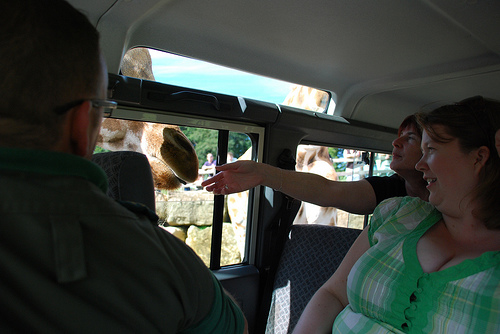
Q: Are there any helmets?
A: No, there are no helmets.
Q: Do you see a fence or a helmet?
A: No, there are no helmets or fences.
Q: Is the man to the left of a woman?
A: Yes, the man is to the left of a woman.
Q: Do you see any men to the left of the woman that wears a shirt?
A: Yes, there is a man to the left of the woman.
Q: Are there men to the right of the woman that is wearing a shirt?
A: No, the man is to the left of the woman.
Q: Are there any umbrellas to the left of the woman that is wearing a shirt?
A: No, there is a man to the left of the woman.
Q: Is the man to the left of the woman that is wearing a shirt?
A: Yes, the man is to the left of the woman.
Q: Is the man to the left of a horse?
A: No, the man is to the left of the woman.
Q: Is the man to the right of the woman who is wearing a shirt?
A: No, the man is to the left of the woman.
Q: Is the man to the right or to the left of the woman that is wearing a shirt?
A: The man is to the left of the woman.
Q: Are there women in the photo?
A: Yes, there is a woman.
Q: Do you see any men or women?
A: Yes, there is a woman.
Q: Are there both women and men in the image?
A: Yes, there are both a woman and a man.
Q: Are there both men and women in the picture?
A: Yes, there are both a woman and a man.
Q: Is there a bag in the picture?
A: No, there are no bags.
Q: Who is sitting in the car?
A: The woman is sitting in the car.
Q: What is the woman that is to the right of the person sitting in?
A: The woman is sitting in the car.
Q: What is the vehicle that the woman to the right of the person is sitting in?
A: The vehicle is a car.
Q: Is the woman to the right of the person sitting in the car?
A: Yes, the woman is sitting in the car.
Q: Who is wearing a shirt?
A: The woman is wearing a shirt.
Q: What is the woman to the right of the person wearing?
A: The woman is wearing a shirt.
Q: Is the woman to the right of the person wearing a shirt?
A: Yes, the woman is wearing a shirt.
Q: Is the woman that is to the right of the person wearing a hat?
A: No, the woman is wearing a shirt.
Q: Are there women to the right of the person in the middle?
A: Yes, there is a woman to the right of the person.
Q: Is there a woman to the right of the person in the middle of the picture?
A: Yes, there is a woman to the right of the person.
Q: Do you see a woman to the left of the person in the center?
A: No, the woman is to the right of the person.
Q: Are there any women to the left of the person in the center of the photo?
A: No, the woman is to the right of the person.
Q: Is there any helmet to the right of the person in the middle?
A: No, there is a woman to the right of the person.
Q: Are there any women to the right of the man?
A: Yes, there is a woman to the right of the man.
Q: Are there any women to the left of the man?
A: No, the woman is to the right of the man.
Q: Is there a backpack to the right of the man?
A: No, there is a woman to the right of the man.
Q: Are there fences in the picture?
A: No, there are no fences.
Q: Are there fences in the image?
A: No, there are no fences.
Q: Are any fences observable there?
A: No, there are no fences.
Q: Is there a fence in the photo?
A: No, there are no fences.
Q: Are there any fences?
A: No, there are no fences.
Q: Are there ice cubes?
A: No, there are no ice cubes.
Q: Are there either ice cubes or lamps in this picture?
A: No, there are no ice cubes or lamps.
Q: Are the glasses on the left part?
A: Yes, the glasses are on the left of the image.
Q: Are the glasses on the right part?
A: No, the glasses are on the left of the image.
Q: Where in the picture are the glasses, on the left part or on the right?
A: The glasses are on the left of the image.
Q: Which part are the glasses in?
A: The glasses are on the left of the image.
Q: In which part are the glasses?
A: The glasses are on the left of the image.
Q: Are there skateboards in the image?
A: No, there are no skateboards.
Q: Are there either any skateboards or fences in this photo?
A: No, there are no skateboards or fences.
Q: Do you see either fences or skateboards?
A: No, there are no skateboards or fences.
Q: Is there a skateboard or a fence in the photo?
A: No, there are no skateboards or fences.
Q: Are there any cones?
A: No, there are no cones.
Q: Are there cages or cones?
A: No, there are no cones or cages.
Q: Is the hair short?
A: Yes, the hair is short.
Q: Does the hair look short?
A: Yes, the hair is short.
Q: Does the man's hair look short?
A: Yes, the hair is short.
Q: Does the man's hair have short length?
A: Yes, the hair is short.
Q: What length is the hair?
A: The hair is short.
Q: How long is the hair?
A: The hair is short.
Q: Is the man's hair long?
A: No, the hair is short.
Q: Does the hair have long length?
A: No, the hair is short.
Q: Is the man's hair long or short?
A: The hair is short.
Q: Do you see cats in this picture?
A: No, there are no cats.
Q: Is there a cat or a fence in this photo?
A: No, there are no cats or fences.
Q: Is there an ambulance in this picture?
A: No, there are no ambulances.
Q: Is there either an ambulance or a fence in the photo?
A: No, there are no ambulances or fences.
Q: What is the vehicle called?
A: The vehicle is a car.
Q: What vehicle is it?
A: The vehicle is a car.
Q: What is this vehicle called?
A: This is a car.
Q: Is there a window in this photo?
A: Yes, there is a window.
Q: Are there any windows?
A: Yes, there is a window.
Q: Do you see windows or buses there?
A: Yes, there is a window.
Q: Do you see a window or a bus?
A: Yes, there is a window.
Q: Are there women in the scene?
A: Yes, there is a woman.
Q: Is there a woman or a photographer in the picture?
A: Yes, there is a woman.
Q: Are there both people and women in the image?
A: Yes, there are both a woman and people.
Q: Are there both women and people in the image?
A: Yes, there are both a woman and people.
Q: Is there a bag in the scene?
A: No, there are no bags.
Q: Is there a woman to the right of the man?
A: Yes, there is a woman to the right of the man.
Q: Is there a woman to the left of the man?
A: No, the woman is to the right of the man.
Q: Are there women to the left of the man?
A: No, the woman is to the right of the man.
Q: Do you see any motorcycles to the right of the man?
A: No, there is a woman to the right of the man.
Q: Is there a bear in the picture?
A: No, there are no bears.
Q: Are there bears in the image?
A: No, there are no bears.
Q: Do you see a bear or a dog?
A: No, there are no bears or dogs.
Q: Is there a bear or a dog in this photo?
A: No, there are no bears or dogs.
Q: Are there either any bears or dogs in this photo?
A: No, there are no bears or dogs.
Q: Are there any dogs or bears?
A: No, there are no bears or dogs.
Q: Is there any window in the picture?
A: Yes, there is a window.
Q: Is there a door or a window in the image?
A: Yes, there is a window.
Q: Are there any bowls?
A: No, there are no bowls.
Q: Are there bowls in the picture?
A: No, there are no bowls.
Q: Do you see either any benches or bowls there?
A: No, there are no bowls or benches.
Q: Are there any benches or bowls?
A: No, there are no bowls or benches.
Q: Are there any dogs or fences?
A: No, there are no fences or dogs.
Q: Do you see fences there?
A: No, there are no fences.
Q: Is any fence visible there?
A: No, there are no fences.